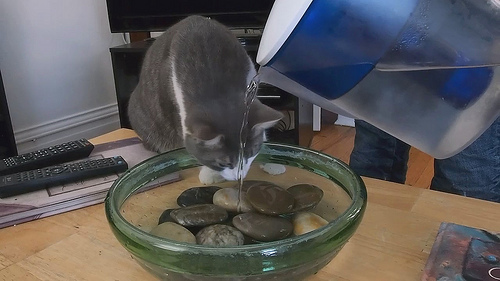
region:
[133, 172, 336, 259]
Rocks in a bowl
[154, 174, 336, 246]
Rocks are in a bowl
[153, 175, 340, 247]
Rocks in a glass bowl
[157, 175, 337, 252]
Rocks are in a glass bowl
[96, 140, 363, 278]
Glass bowl on a table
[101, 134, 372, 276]
Glass bowl is on a table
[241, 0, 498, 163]
Container of water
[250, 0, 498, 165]
Plastic container of water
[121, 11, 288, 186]
Cat is drinking water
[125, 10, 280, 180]
Gray and white cat is drinking water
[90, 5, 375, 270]
cat licking water out of bowl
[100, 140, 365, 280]
glass bowl with rocks in it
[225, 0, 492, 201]
someone is pouring water into the bowl with rocks in it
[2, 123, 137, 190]
two remote controllers on the side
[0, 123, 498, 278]
light colored wooden table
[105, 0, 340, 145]
black appliances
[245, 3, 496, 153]
water filter container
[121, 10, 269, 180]
cat drinking filtered water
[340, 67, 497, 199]
person pouring water is wearing jeans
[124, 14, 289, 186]
cat drinking water from bowl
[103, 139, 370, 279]
glass bowl with rocks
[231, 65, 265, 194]
water pouring from pitcher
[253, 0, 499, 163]
pitcher full of water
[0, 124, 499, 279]
table with woodgrain surface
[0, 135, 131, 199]
two remote controls for electronics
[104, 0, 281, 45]
television on top of stand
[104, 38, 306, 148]
stand with television on top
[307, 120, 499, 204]
floor made of hardwood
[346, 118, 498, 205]
person's legs covered with blue jeans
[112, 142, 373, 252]
rock in a glass bowl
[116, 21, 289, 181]
cat leaning in bowl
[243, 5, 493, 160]
pitcher with cold water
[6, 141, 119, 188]
two black remotes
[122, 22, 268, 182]
cat on top of table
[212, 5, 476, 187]
water being poured into bowl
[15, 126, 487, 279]
table made from light wood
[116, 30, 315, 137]
black television stand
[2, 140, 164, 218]
remotes on top of book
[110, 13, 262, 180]
gray and white cat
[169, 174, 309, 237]
wet river rocks in a bowl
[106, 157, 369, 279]
a glass bowl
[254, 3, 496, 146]
a pitcher of cold water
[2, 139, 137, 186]
black remote controls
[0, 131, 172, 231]
a purple ledger on the table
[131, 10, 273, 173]
a fluffy gray cat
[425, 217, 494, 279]
a book on the table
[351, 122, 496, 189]
blue jeans covering legs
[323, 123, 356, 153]
a wooden floor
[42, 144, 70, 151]
black buttons on the remote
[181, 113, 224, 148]
Ear of a cat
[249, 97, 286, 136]
Ear of a cat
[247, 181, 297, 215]
the rock is smooth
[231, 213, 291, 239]
the rock is gray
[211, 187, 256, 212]
the rock is light gray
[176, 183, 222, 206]
the rock is black